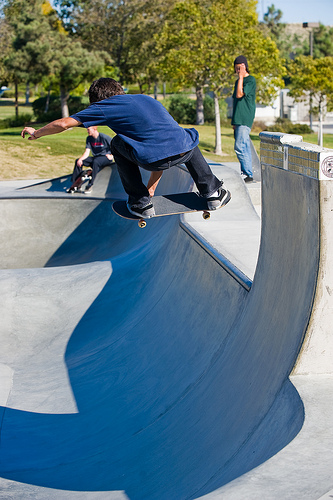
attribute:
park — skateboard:
[38, 82, 331, 380]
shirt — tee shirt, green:
[229, 72, 255, 124]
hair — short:
[86, 73, 126, 104]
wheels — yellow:
[134, 210, 212, 227]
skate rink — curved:
[0, 130, 331, 498]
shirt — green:
[230, 69, 257, 130]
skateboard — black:
[100, 168, 249, 232]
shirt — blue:
[67, 90, 202, 163]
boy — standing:
[228, 55, 261, 181]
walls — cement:
[93, 126, 329, 499]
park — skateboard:
[1, 3, 92, 44]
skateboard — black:
[109, 192, 232, 227]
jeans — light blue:
[234, 119, 257, 183]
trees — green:
[0, 4, 332, 120]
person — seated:
[56, 118, 112, 195]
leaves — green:
[157, 30, 259, 72]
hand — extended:
[17, 121, 52, 145]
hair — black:
[85, 75, 128, 101]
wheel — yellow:
[134, 219, 148, 229]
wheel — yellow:
[200, 208, 213, 221]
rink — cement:
[0, 153, 250, 291]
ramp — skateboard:
[0, 131, 333, 496]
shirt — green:
[233, 75, 257, 129]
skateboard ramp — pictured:
[4, 131, 332, 496]